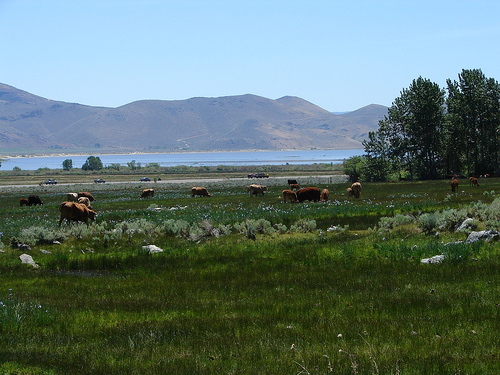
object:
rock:
[141, 244, 164, 255]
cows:
[55, 200, 99, 230]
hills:
[2, 82, 365, 157]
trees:
[365, 71, 456, 184]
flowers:
[222, 211, 226, 215]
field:
[0, 178, 499, 375]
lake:
[0, 148, 382, 170]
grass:
[432, 353, 448, 374]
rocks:
[15, 253, 41, 271]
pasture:
[0, 159, 500, 225]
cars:
[44, 178, 58, 185]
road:
[3, 173, 347, 183]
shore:
[5, 145, 361, 156]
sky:
[0, 10, 500, 115]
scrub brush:
[10, 229, 41, 250]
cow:
[189, 185, 212, 198]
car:
[93, 178, 106, 184]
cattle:
[6, 172, 492, 228]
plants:
[289, 217, 317, 233]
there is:
[46, 106, 114, 135]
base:
[0, 141, 378, 161]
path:
[175, 128, 210, 151]